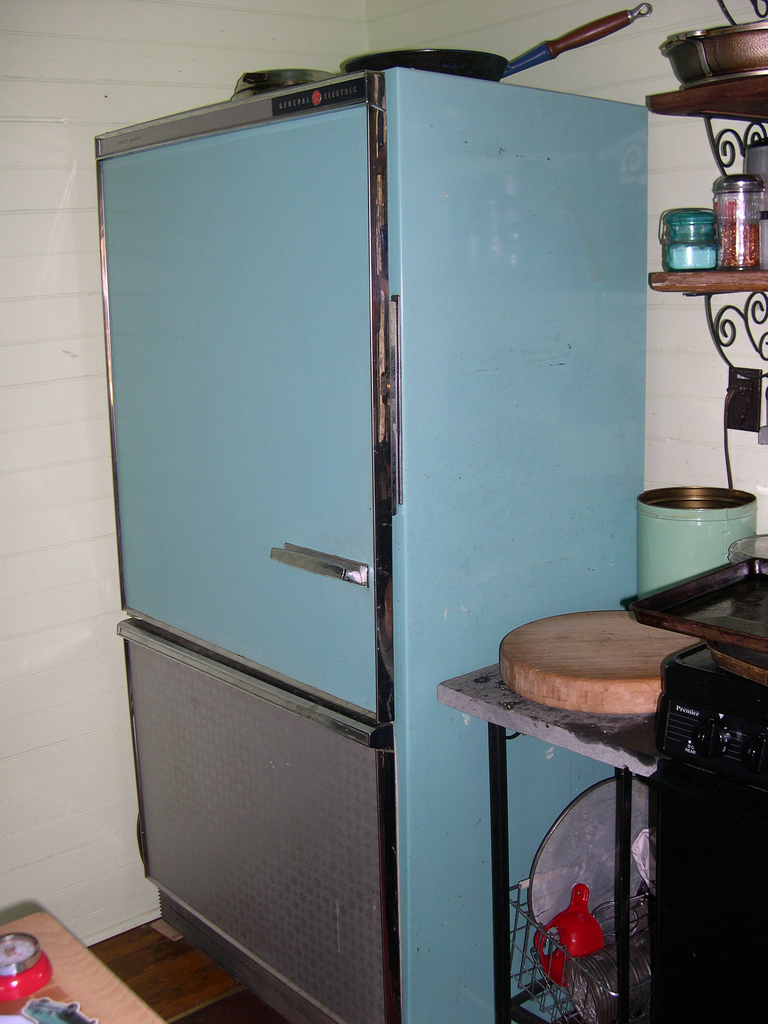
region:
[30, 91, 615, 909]
this is a kitchen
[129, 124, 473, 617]
the fridge is large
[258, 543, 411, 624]
the handle is metal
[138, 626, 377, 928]
the freezer is gray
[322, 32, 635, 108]
the skillet is on the fridge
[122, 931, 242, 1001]
the floor is wooden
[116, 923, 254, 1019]
the floor is brown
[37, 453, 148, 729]
the wall is tiled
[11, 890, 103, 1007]
a view of table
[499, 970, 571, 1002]
a view of iron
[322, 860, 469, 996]
line in the fridge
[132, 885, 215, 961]
a view of stone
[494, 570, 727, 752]
a view of table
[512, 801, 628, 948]
a view of plate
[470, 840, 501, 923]
leg of the table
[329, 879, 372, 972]
drawer on the fridge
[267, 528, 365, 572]
handle on the fridge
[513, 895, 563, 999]
basket on the table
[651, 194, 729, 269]
bottle on the shelf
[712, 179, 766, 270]
jar on the shelf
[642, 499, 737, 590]
jar on the table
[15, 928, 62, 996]
clock on the table